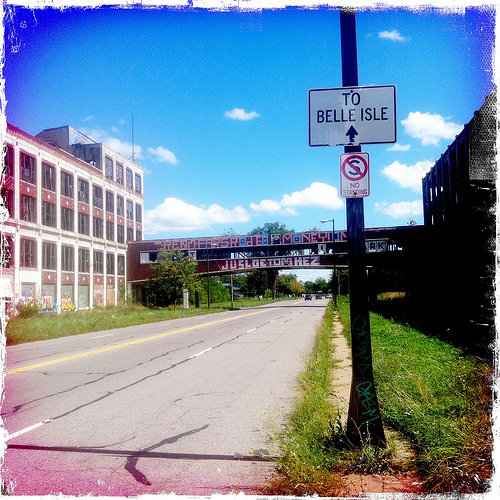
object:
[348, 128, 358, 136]
black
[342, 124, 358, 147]
arrow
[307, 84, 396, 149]
sign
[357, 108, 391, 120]
isle"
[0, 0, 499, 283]
sky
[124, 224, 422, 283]
bridge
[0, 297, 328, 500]
street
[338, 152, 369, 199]
sign